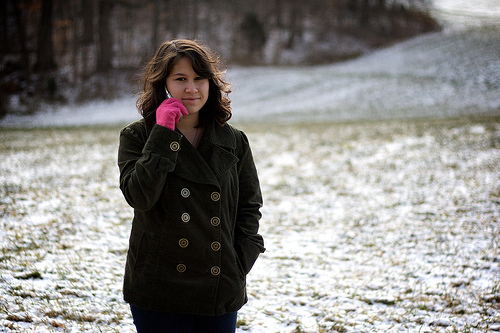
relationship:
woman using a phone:
[118, 39, 267, 333] [163, 85, 183, 123]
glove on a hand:
[156, 98, 188, 131] [156, 97, 188, 131]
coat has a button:
[118, 109, 267, 316] [181, 188, 190, 198]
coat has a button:
[118, 109, 267, 316] [181, 212, 191, 223]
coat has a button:
[118, 109, 267, 316] [178, 238, 189, 248]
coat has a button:
[118, 109, 267, 316] [177, 263, 187, 273]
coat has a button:
[118, 109, 267, 316] [210, 191, 221, 201]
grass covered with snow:
[0, 0, 499, 333] [1, 0, 500, 332]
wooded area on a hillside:
[0, 0, 443, 121] [0, 0, 499, 127]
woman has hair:
[118, 39, 267, 333] [130, 37, 237, 129]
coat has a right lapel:
[118, 109, 267, 316] [144, 108, 221, 187]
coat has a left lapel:
[118, 109, 267, 316] [196, 117, 240, 178]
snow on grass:
[1, 0, 500, 332] [0, 0, 499, 333]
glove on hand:
[156, 98, 188, 131] [156, 97, 188, 131]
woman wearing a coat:
[118, 39, 267, 333] [118, 109, 267, 316]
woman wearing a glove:
[118, 39, 267, 333] [156, 98, 188, 131]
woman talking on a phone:
[118, 39, 267, 333] [163, 85, 183, 123]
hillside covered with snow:
[0, 0, 499, 127] [1, 0, 500, 332]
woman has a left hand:
[118, 39, 267, 333] [236, 245, 258, 268]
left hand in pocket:
[236, 245, 258, 268] [233, 237, 260, 273]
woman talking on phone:
[118, 39, 267, 333] [163, 85, 183, 123]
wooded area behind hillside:
[0, 0, 443, 121] [0, 0, 499, 127]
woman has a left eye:
[118, 39, 267, 333] [194, 76, 204, 81]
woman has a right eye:
[118, 39, 267, 333] [176, 77, 188, 82]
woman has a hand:
[118, 39, 267, 333] [156, 97, 188, 131]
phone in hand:
[163, 85, 183, 123] [156, 97, 188, 131]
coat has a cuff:
[118, 109, 267, 316] [144, 123, 183, 163]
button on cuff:
[170, 140, 180, 151] [144, 123, 183, 163]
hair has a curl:
[130, 37, 237, 129] [136, 90, 155, 115]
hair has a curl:
[130, 37, 237, 129] [218, 104, 232, 125]